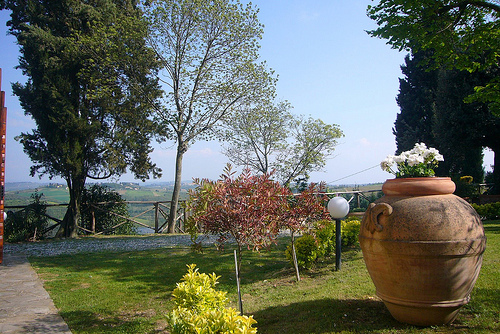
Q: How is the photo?
A: Clear.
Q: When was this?
A: Daytime.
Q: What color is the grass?
A: Green.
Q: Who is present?
A: Nobody.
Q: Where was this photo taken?
A: Near the flowers.